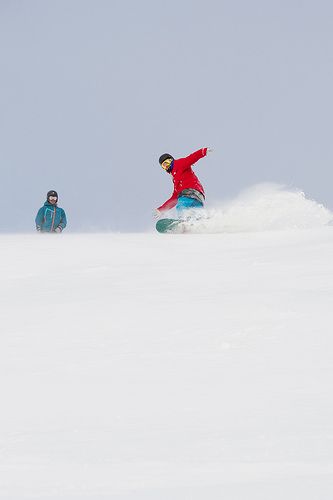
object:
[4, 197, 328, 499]
snow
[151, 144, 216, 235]
person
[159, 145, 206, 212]
jacket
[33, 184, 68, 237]
person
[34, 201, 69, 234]
jacket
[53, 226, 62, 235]
glove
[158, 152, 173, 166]
cap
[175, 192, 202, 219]
pants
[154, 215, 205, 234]
snowboard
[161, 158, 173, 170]
goggles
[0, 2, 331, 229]
sky